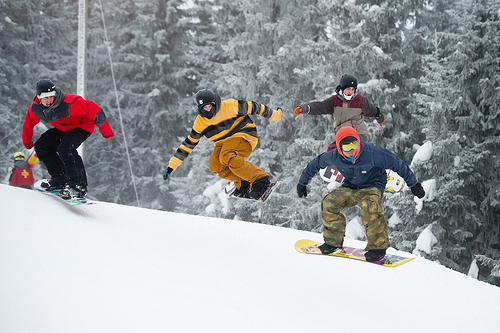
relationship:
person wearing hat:
[160, 88, 285, 203] [194, 87, 221, 119]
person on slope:
[19, 78, 118, 200] [2, 177, 498, 332]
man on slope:
[294, 126, 427, 264] [2, 177, 498, 332]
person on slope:
[160, 88, 285, 203] [2, 177, 498, 332]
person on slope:
[290, 74, 387, 156] [2, 177, 498, 332]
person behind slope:
[6, 151, 36, 189] [2, 177, 498, 332]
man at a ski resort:
[294, 126, 427, 264] [3, 0, 493, 331]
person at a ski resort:
[287, 75, 387, 137] [3, 0, 493, 331]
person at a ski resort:
[160, 88, 285, 203] [3, 0, 493, 331]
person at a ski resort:
[19, 78, 118, 200] [3, 0, 493, 331]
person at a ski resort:
[6, 151, 36, 190] [3, 0, 493, 331]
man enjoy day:
[294, 126, 427, 264] [7, 5, 497, 329]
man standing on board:
[294, 126, 427, 264] [294, 236, 416, 267]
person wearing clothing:
[19, 78, 118, 200] [48, 107, 82, 182]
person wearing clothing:
[160, 88, 285, 203] [213, 102, 243, 161]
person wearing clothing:
[290, 74, 387, 156] [326, 97, 373, 122]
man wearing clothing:
[294, 126, 427, 264] [340, 166, 390, 246]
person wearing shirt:
[188, 90, 261, 187] [186, 113, 259, 138]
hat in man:
[334, 125, 359, 160] [294, 127, 424, 256]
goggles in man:
[338, 140, 358, 150] [294, 127, 424, 256]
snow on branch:
[409, 140, 439, 256] [406, 138, 466, 166]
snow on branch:
[409, 140, 439, 256] [414, 175, 474, 209]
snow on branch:
[409, 140, 439, 256] [439, 175, 474, 210]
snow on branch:
[409, 140, 439, 256] [411, 218, 456, 260]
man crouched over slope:
[294, 127, 424, 256] [0, 217, 496, 330]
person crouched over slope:
[19, 78, 118, 200] [0, 217, 496, 330]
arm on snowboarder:
[381, 141, 423, 185] [294, 121, 431, 265]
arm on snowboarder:
[291, 150, 328, 200] [294, 121, 431, 265]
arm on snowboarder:
[362, 96, 386, 126] [292, 67, 389, 135]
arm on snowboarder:
[288, 96, 329, 120] [292, 67, 389, 135]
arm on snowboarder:
[160, 120, 200, 178] [160, 81, 284, 198]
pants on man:
[41, 130, 93, 188] [33, 56, 103, 187]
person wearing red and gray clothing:
[13, 68, 125, 213] [20, 94, 118, 151]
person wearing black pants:
[19, 78, 118, 200] [43, 127, 98, 192]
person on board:
[19, 78, 118, 200] [30, 179, 89, 207]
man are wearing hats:
[294, 126, 427, 264] [314, 52, 374, 174]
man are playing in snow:
[294, 126, 427, 264] [155, 220, 265, 301]